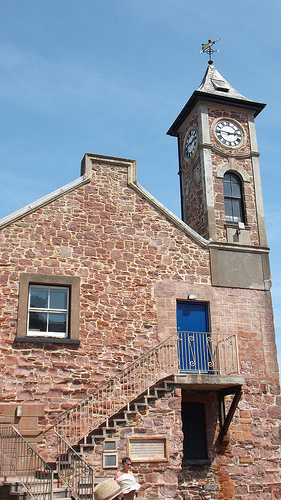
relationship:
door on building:
[178, 300, 210, 371] [4, 62, 276, 498]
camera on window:
[234, 220, 248, 239] [220, 168, 248, 229]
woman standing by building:
[116, 456, 133, 483] [4, 62, 276, 498]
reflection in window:
[26, 293, 48, 313] [26, 282, 70, 339]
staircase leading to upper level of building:
[0, 333, 245, 500] [4, 62, 276, 498]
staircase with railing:
[0, 333, 245, 500] [1, 330, 241, 498]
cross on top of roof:
[199, 39, 221, 63] [186, 62, 255, 100]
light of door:
[184, 292, 204, 300] [172, 291, 218, 375]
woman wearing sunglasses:
[113, 455, 143, 498] [124, 462, 132, 466]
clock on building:
[209, 113, 247, 151] [4, 62, 276, 498]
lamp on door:
[188, 294, 197, 300] [174, 297, 210, 374]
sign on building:
[125, 434, 169, 463] [4, 62, 276, 498]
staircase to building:
[13, 406, 78, 492] [4, 62, 276, 498]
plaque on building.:
[121, 433, 182, 467] [7, 14, 279, 412]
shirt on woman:
[115, 470, 132, 474] [109, 453, 141, 498]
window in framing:
[20, 269, 85, 351] [69, 269, 87, 349]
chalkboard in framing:
[101, 451, 118, 469] [114, 439, 120, 468]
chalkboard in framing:
[103, 439, 115, 453] [114, 439, 120, 468]